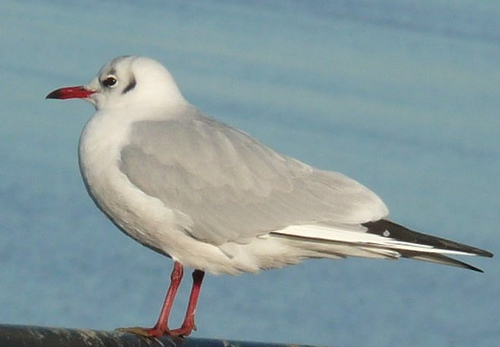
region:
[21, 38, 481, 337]
bird on a bird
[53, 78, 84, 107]
beak of the bird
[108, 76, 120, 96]
eye of the bird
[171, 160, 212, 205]
feather of the bird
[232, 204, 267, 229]
feather of the bird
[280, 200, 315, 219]
feather of the bird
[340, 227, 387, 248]
feather of the bird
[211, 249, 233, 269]
feather of the bird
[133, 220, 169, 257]
feather of the bird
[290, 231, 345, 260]
feather of the bird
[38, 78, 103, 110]
Orange and black beak on a bird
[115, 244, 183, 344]
Small red leg on a bird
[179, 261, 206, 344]
Small red leg on a bird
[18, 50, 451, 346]
Small bird standing on a black metal post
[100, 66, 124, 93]
Black and white eye on a bird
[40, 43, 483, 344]
Small bird standing outside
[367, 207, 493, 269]
Long black feathers on a bird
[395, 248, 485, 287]
Long black feathers on a bird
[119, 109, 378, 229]
Grey feathers on a bird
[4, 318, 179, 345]
Long black metal post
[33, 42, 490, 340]
this is a bird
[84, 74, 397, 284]
the bird is white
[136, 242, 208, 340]
the legs are red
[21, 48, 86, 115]
the beak is red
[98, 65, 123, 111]
this is an eye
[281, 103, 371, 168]
the sky is cloudy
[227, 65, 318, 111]
the sky is cloudy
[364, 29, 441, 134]
the sky is cloudy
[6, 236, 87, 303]
the sky is cloudy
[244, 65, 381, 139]
the sky is cloudy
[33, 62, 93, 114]
the beak of a bird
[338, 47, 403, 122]
this is the sky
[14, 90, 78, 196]
this is the sky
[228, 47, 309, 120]
this is the sky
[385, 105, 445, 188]
this is the sky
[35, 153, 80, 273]
this is the sky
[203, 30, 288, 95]
this is the sky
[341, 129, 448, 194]
this is the sky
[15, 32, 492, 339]
bird on the perch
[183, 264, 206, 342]
leg of the bird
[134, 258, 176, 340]
leg of the bird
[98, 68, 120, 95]
eye of the bird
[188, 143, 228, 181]
feathers of the bird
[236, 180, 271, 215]
feathers of the bird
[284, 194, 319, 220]
feathers of the bird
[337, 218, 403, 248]
feathers of the fird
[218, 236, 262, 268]
feathers of the bird